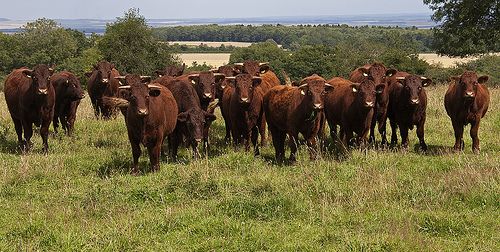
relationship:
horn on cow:
[143, 80, 161, 91] [111, 78, 179, 174]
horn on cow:
[116, 83, 131, 92] [111, 78, 179, 174]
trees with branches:
[85, 100, 497, 212] [78, 31, 184, 67]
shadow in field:
[216, 149, 478, 249] [0, 24, 497, 251]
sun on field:
[3, 4, 494, 39] [0, 81, 484, 246]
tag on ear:
[301, 86, 307, 95] [295, 82, 309, 92]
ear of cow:
[295, 82, 309, 92] [259, 74, 336, 165]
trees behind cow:
[2, 4, 189, 87] [115, 80, 183, 170]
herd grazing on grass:
[10, 52, 490, 151] [0, 84, 500, 252]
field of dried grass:
[0, 81, 484, 246] [168, 50, 230, 67]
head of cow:
[118, 82, 163, 113] [115, 80, 183, 170]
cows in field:
[3, 56, 490, 176] [0, 79, 500, 250]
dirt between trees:
[167, 37, 234, 67] [263, 40, 362, 75]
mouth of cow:
[309, 96, 329, 114] [258, 80, 332, 153]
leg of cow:
[127, 139, 142, 173] [115, 77, 181, 176]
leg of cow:
[146, 133, 162, 170] [115, 77, 181, 176]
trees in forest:
[278, 24, 370, 50] [158, 7, 468, 92]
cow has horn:
[118, 82, 178, 172] [116, 84, 130, 89]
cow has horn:
[118, 82, 178, 172] [146, 84, 162, 89]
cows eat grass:
[3, 56, 490, 176] [31, 166, 399, 249]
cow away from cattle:
[442, 66, 492, 156] [387, 74, 434, 156]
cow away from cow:
[442, 66, 492, 156] [347, 57, 398, 153]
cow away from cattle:
[442, 66, 492, 156] [324, 76, 387, 155]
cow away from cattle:
[442, 66, 492, 156] [261, 79, 335, 167]